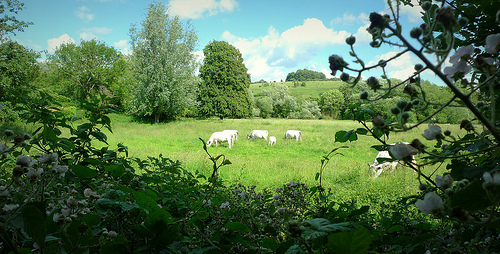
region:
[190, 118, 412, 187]
a herd of cows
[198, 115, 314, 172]
the cows are white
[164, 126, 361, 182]
the pasture is lush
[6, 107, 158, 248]
flowers are in the foreground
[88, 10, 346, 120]
trees are in the background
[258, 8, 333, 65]
the sky has puffy white clouds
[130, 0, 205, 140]
this tree is taller than the rest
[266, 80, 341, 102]
another meadow is in the background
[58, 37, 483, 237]
it appears to be early spring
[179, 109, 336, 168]
the cows are grazing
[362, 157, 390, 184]
the head of a cow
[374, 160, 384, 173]
the ear of a cow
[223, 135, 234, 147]
the hind legs of a cow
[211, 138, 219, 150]
the front leg of a cow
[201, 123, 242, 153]
a white cow on the grass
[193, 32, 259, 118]
a large green tree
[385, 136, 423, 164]
a white flower on the plant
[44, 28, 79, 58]
a white cloud in the sky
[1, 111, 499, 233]
a grassy green field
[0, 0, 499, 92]
a cloudy blue sky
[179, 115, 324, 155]
Several sheep are together.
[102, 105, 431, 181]
The sheep are in a field.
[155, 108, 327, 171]
The sheep are grazing.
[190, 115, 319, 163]
The sheep are white.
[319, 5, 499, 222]
The plant has flowers.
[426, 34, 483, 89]
The flowers are white.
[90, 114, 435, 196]
The field is lush.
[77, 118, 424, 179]
The field is green.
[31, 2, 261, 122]
Many trees line the field.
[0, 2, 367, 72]
The sky is blue.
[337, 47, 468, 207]
the flowers are white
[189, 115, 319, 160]
the animals are grazing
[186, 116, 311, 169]
the animals are all white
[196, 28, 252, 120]
the tree is full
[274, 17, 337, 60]
the cloud is bright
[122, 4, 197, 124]
the tree is tall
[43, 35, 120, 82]
the tree is wide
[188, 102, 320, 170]
the cows are hungry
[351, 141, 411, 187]
the cow is alone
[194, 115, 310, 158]
these cows are together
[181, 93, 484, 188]
Animals in the field.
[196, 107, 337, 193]
White animals on the field.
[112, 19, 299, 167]
Trees in the field.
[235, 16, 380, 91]
White clouds in the sky.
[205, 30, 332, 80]
White clouds in the blue sky.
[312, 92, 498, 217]
Leaves on the tree.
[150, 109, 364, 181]
Grass on the field.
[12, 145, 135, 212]
Flowers on the plants.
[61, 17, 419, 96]
Blue sky with white fluffy clouds.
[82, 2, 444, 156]
Rolling hills in the background.